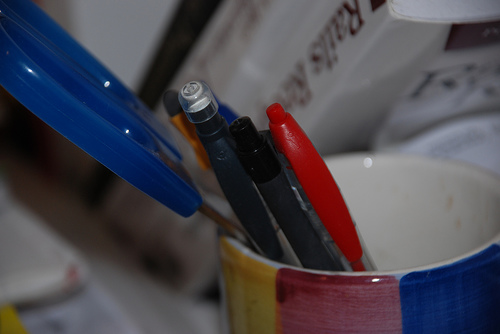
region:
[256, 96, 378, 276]
a red plastic pen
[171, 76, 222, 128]
a clear eraser cap on a pencil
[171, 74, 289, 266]
a black mechanical pencil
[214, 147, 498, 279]
the mouth of a coffee mug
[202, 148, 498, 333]
a multi-colored coffee mug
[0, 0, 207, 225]
the blue handle of a pair of scissors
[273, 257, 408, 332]
red paint on the cup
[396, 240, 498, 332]
blue paint on the cup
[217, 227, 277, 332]
yellow paint on the cup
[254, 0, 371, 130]
black writing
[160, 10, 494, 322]
A container with writing tools.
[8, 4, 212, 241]
A pair of blue handled scissors.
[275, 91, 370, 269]
An orange writing tool.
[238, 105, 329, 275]
A grey and black pen.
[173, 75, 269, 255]
A grey pen with clear top.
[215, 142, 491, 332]
A round striped container.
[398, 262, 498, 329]
Wide blue stripe on container.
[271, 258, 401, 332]
Wide pink stripe on container.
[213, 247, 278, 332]
Wide yellow stripe on container.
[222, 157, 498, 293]
The inside of container is white.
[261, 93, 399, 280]
a plastic red pen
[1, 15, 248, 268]
a pair of blue handled scissors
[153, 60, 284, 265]
a mechanical pencil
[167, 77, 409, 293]
a few assorted writing tools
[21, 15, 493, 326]
some office supplies in a cup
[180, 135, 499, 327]
a colorful coffee cup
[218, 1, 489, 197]
a black and white book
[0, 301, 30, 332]
a bright yellow paper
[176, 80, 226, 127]
a clear plastic cap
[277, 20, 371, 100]
some blurry black writing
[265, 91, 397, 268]
red pen in a colorful mug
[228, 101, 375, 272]
black pen and red pen in a mug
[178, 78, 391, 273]
three pens in a mug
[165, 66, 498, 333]
pens in a mug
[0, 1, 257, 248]
blue scissors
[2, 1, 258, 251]
blue scissors in a mug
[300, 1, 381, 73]
blurry burgundy text print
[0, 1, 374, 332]
blue scissors and pens in a mug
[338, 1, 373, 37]
the letter R printed in burgundy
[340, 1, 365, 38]
the letter R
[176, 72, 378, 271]
Pens in a pen tin.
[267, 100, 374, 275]
Red pen in a pen tin.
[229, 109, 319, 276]
Black and grey pen in a pen tin.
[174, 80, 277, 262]
Pen with a white top in a pen tin.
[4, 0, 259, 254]
Scissors with blue handle in a pen tin.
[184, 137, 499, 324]
Pen tins with pens in it.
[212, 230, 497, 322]
Pen tin that is blue, red and yellow in color.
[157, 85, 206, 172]
Yellow pen in a pen tin.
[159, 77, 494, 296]
The cup is white color from the inside.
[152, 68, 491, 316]
Many pens in a cup.